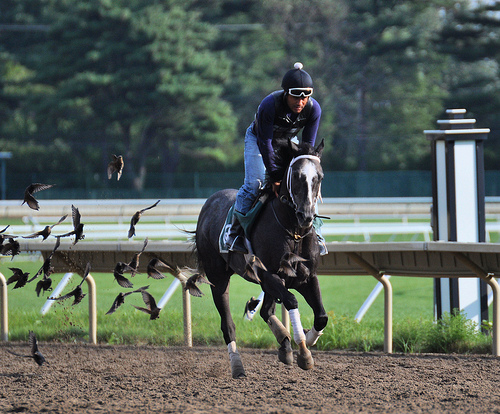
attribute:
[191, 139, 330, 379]
horse — dark brown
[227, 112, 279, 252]
pants — grey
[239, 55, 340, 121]
helmet — black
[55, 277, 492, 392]
course — dark brown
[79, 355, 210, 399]
surfaces — dirt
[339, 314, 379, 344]
surfaces — grass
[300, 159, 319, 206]
stripe — white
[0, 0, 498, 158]
leaves — green